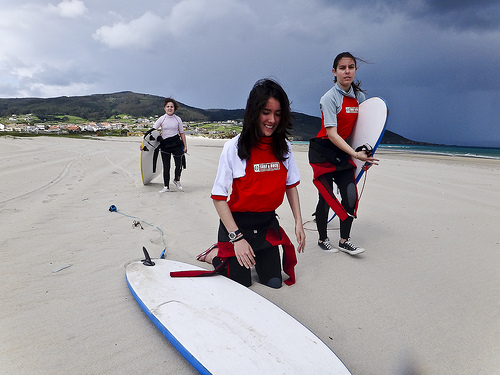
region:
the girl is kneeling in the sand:
[195, 67, 316, 285]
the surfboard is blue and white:
[115, 232, 350, 367]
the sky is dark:
[291, 1, 496, 146]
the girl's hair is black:
[222, 60, 292, 160]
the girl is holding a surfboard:
[310, 50, 395, 180]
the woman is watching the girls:
[130, 76, 206, 191]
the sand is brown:
[10, 136, 498, 373]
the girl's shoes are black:
[307, 223, 381, 268]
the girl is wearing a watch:
[213, 216, 255, 262]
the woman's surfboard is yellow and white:
[130, 127, 170, 193]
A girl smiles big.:
[251, 79, 286, 141]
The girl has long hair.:
[237, 68, 289, 160]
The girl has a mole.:
[259, 114, 265, 119]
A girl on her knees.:
[196, 77, 309, 290]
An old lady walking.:
[146, 100, 187, 193]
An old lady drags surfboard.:
[139, 96, 187, 193]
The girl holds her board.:
[306, 44, 381, 263]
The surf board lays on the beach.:
[108, 246, 353, 374]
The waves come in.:
[402, 148, 499, 163]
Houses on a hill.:
[8, 114, 242, 135]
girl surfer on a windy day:
[300, 39, 399, 270]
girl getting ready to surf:
[304, 46, 406, 261]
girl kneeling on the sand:
[208, 79, 307, 307]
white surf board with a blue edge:
[103, 239, 353, 371]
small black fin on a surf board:
[125, 240, 162, 277]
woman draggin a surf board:
[131, 91, 195, 199]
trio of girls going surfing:
[102, 45, 424, 356]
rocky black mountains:
[25, 83, 148, 105]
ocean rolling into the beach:
[414, 137, 490, 178]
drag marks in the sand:
[19, 154, 79, 233]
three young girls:
[119, 21, 428, 276]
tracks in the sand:
[3, 137, 122, 244]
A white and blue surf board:
[110, 228, 311, 372]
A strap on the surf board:
[105, 196, 185, 256]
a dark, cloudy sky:
[0, 0, 484, 148]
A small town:
[11, 107, 188, 136]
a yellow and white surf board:
[141, 130, 166, 185]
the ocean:
[382, 135, 499, 161]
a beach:
[6, 136, 496, 373]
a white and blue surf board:
[327, 80, 395, 239]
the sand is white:
[68, 182, 175, 315]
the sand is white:
[57, 245, 162, 370]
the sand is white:
[17, 193, 136, 339]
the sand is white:
[345, 231, 412, 348]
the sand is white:
[356, 260, 408, 322]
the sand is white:
[70, 220, 147, 310]